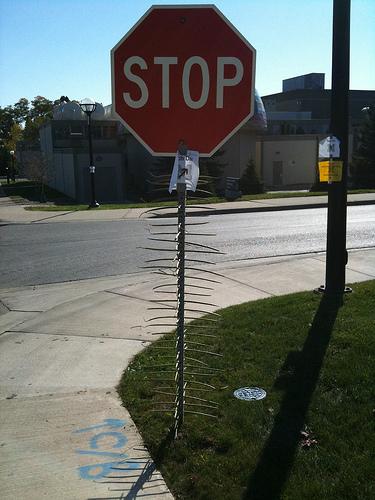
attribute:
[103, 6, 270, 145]
sign — stop, taped, red, white, octagonal, posted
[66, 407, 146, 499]
graffiti — blue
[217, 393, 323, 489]
grass — green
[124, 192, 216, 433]
post — white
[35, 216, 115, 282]
road — asphalt, dark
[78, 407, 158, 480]
letter — blue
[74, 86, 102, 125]
bulb — round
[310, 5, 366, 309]
pole — telephone, shadow, light, grey, street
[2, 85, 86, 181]
tree — next, green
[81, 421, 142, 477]
arrow — blue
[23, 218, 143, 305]
street — no cars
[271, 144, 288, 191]
door — closed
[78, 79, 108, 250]
lamp — black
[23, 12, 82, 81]
sky — blue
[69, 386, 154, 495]
paint — blue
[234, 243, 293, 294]
sidewalk — brown